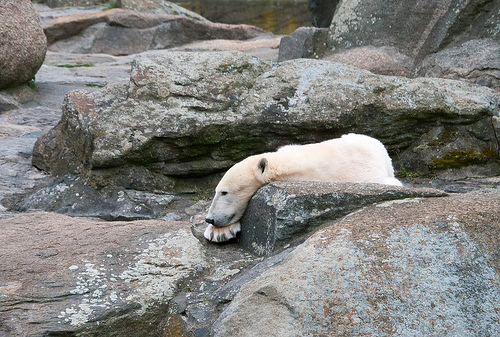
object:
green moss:
[57, 61, 96, 70]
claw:
[201, 224, 242, 243]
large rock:
[30, 51, 499, 188]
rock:
[235, 179, 450, 257]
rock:
[157, 188, 500, 336]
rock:
[0, 206, 211, 337]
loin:
[296, 139, 371, 180]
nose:
[201, 214, 215, 226]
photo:
[0, 0, 499, 335]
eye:
[218, 189, 228, 197]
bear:
[202, 133, 407, 244]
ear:
[255, 157, 272, 182]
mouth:
[209, 213, 240, 228]